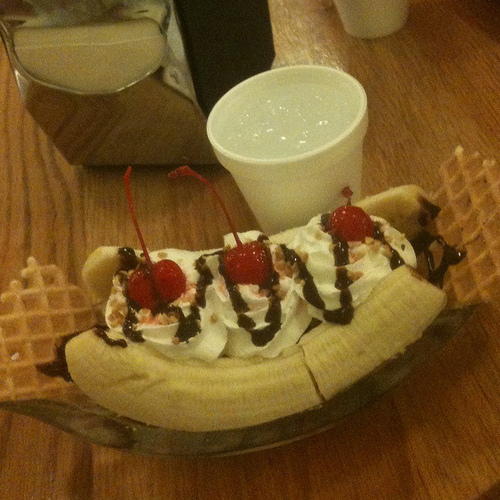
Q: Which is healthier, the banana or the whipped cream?
A: The banana is healthier than the whipped cream.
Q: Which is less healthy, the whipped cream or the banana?
A: The whipped cream is less healthy than the banana.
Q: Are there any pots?
A: No, there are no pots.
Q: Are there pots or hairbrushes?
A: No, there are no pots or hairbrushes.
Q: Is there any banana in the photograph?
A: Yes, there is a banana.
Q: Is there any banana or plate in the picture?
A: Yes, there is a banana.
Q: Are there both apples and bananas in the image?
A: No, there is a banana but no apples.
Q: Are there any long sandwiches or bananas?
A: Yes, there is a long banana.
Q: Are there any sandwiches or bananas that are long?
A: Yes, the banana is long.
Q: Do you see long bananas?
A: Yes, there is a long banana.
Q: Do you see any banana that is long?
A: Yes, there is a banana that is long.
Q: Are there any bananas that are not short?
A: Yes, there is a long banana.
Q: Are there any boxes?
A: No, there are no boxes.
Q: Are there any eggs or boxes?
A: No, there are no boxes or eggs.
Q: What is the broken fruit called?
A: The fruit is a banana.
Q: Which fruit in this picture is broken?
A: The fruit is a banana.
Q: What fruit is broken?
A: The fruit is a banana.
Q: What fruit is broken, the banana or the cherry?
A: The banana is broken.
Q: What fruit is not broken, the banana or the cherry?
A: The cherry is not broken.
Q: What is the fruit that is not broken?
A: The fruit is a cherry.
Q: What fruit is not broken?
A: The fruit is a cherry.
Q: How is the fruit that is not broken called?
A: The fruit is a cherry.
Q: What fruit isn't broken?
A: The fruit is a cherry.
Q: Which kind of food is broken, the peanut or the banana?
A: The banana is broken.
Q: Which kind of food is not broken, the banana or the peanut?
A: The peanut is not broken.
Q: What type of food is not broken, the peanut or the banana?
A: The peanut is not broken.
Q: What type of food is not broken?
A: The food is a peanut.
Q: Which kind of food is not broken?
A: The food is a peanut.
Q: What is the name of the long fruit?
A: The fruit is a banana.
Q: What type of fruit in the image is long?
A: The fruit is a banana.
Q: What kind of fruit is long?
A: The fruit is a banana.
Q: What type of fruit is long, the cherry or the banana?
A: The banana is long.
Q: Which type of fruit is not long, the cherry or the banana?
A: The cherry is not long.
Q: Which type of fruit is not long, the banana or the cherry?
A: The cherry is not long.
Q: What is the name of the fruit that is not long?
A: The fruit is a cherry.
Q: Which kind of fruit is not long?
A: The fruit is a cherry.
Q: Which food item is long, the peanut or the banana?
A: The banana is long.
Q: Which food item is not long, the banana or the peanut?
A: The peanut is not long.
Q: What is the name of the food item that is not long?
A: The food item is a peanut.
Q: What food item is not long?
A: The food item is a peanut.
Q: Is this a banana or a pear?
A: This is a banana.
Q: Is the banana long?
A: Yes, the banana is long.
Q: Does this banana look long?
A: Yes, the banana is long.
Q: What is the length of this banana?
A: The banana is long.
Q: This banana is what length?
A: The banana is long.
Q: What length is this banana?
A: The banana is long.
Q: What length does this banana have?
A: The banana has long length.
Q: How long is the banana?
A: The banana is long.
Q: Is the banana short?
A: No, the banana is long.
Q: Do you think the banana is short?
A: No, the banana is long.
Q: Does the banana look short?
A: No, the banana is long.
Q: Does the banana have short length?
A: No, the banana is long.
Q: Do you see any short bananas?
A: No, there is a banana but it is long.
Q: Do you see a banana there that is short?
A: No, there is a banana but it is long.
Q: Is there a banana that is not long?
A: No, there is a banana but it is long.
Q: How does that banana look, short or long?
A: The banana is long.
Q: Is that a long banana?
A: Yes, that is a long banana.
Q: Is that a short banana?
A: No, that is a long banana.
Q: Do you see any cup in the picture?
A: Yes, there is a cup.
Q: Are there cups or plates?
A: Yes, there is a cup.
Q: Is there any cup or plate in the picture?
A: Yes, there is a cup.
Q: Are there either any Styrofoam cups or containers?
A: Yes, there is a Styrofoam cup.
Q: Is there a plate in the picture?
A: No, there are no plates.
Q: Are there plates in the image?
A: No, there are no plates.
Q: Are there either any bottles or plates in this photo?
A: No, there are no plates or bottles.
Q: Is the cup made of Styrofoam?
A: Yes, the cup is made of styrofoam.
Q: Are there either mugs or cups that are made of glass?
A: No, there is a cup but it is made of styrofoam.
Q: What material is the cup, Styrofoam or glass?
A: The cup is made of styrofoam.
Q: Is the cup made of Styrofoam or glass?
A: The cup is made of styrofoam.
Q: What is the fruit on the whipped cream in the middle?
A: The fruit is a cherry.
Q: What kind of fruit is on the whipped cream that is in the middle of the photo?
A: The fruit is a cherry.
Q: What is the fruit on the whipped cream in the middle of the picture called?
A: The fruit is a cherry.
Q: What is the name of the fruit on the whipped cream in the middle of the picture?
A: The fruit is a cherry.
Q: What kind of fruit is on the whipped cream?
A: The fruit is a cherry.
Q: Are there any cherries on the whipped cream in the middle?
A: Yes, there is a cherry on the whipped cream.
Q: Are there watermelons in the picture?
A: No, there are no watermelons.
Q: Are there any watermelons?
A: No, there are no watermelons.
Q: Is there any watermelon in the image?
A: No, there are no watermelons.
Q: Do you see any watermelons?
A: No, there are no watermelons.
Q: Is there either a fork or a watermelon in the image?
A: No, there are no watermelons or forks.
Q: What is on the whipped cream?
A: The cherry is on the whipped cream.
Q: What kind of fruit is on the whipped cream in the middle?
A: The fruit is a cherry.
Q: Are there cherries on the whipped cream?
A: Yes, there is a cherry on the whipped cream.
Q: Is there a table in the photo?
A: Yes, there is a table.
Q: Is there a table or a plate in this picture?
A: Yes, there is a table.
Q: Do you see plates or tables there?
A: Yes, there is a table.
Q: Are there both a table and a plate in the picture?
A: No, there is a table but no plates.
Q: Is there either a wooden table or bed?
A: Yes, there is a wood table.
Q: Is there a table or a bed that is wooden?
A: Yes, the table is wooden.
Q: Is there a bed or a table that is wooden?
A: Yes, the table is wooden.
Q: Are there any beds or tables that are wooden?
A: Yes, the table is wooden.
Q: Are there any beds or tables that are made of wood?
A: Yes, the table is made of wood.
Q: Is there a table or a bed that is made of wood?
A: Yes, the table is made of wood.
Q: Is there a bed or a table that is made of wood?
A: Yes, the table is made of wood.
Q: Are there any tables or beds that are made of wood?
A: Yes, the table is made of wood.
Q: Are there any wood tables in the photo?
A: Yes, there is a wood table.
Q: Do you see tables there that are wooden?
A: Yes, there is a table that is wooden.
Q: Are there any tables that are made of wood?
A: Yes, there is a table that is made of wood.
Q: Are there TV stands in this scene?
A: No, there are no TV stands.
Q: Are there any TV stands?
A: No, there are no TV stands.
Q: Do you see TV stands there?
A: No, there are no TV stands.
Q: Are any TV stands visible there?
A: No, there are no TV stands.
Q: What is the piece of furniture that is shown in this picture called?
A: The piece of furniture is a table.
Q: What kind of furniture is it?
A: The piece of furniture is a table.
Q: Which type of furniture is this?
A: That is a table.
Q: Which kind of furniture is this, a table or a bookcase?
A: That is a table.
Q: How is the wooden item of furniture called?
A: The piece of furniture is a table.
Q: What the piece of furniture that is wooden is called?
A: The piece of furniture is a table.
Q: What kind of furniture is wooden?
A: The furniture is a table.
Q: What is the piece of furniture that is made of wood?
A: The piece of furniture is a table.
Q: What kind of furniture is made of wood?
A: The furniture is a table.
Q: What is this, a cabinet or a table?
A: This is a table.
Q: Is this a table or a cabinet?
A: This is a table.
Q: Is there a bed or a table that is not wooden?
A: No, there is a table but it is wooden.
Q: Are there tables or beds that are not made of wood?
A: No, there is a table but it is made of wood.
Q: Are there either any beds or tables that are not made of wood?
A: No, there is a table but it is made of wood.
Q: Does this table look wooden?
A: Yes, the table is wooden.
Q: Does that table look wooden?
A: Yes, the table is wooden.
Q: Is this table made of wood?
A: Yes, the table is made of wood.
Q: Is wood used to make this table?
A: Yes, the table is made of wood.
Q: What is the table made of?
A: The table is made of wood.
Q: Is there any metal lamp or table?
A: No, there is a table but it is wooden.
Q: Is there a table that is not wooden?
A: No, there is a table but it is wooden.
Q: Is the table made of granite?
A: No, the table is made of wood.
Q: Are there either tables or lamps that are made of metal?
A: No, there is a table but it is made of wood.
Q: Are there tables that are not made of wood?
A: No, there is a table but it is made of wood.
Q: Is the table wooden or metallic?
A: The table is wooden.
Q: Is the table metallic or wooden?
A: The table is wooden.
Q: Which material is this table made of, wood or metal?
A: The table is made of wood.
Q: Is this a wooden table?
A: Yes, this is a wooden table.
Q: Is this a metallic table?
A: No, this is a wooden table.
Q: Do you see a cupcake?
A: No, there are no cupcakes.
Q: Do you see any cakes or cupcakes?
A: No, there are no cupcakes or cakes.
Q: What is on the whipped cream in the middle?
A: The cherry is on the whipped cream.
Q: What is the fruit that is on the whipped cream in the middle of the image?
A: The fruit is a cherry.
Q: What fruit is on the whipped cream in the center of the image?
A: The fruit is a cherry.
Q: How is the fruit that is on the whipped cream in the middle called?
A: The fruit is a cherry.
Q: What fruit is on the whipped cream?
A: The fruit is a cherry.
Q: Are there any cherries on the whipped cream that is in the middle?
A: Yes, there is a cherry on the whipped cream.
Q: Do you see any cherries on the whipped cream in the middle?
A: Yes, there is a cherry on the whipped cream.